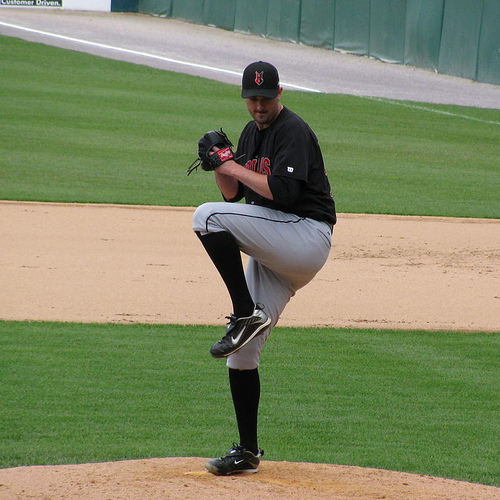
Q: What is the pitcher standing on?
A: One leg.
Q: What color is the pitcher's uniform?
A: Black, red and grey.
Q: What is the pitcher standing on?
A: Pitchers mound.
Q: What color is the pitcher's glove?
A: Black.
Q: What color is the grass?
A: Green.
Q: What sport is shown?
A: Baseball.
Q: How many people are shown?
A: One.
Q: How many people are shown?
A: 1.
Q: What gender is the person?
A: Male.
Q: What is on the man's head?
A: Cap.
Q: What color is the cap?
A: Black.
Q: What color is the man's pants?
A: Gray.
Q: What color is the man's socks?
A: Black.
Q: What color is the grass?
A: Green.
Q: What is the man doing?
A: Pitching.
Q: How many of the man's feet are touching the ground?
A: 1.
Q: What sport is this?
A: Baseball.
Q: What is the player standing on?
A: Mound.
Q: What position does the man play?
A: Pitcher.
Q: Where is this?
A: Baseball diamond.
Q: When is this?
A: During game.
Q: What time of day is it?
A: Afternoon.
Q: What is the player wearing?
A: Uniform.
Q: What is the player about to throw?
A: Baseball.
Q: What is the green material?
A: AstroTurf.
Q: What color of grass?
A: Green.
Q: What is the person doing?
A: Pitching a ball.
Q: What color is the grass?
A: Green.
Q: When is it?
A: Day time.